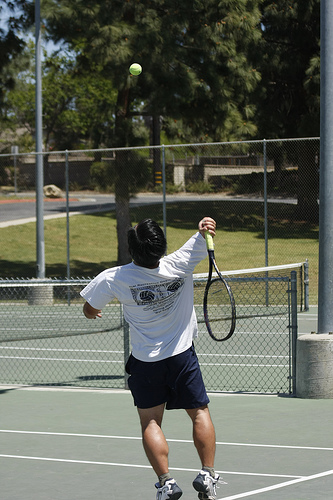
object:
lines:
[0, 427, 333, 500]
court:
[0, 134, 331, 498]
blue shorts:
[125, 340, 210, 410]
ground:
[264, 97, 288, 120]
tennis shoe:
[192, 467, 227, 500]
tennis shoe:
[155, 477, 183, 500]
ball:
[129, 63, 142, 75]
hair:
[127, 218, 167, 266]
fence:
[0, 259, 309, 397]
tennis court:
[0, 385, 333, 500]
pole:
[317, 0, 332, 333]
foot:
[192, 471, 220, 500]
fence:
[0, 136, 321, 393]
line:
[216, 442, 332, 451]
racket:
[203, 230, 236, 341]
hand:
[198, 216, 216, 238]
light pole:
[34, 0, 46, 281]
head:
[127, 218, 167, 265]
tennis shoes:
[155, 469, 227, 499]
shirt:
[79, 232, 210, 364]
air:
[0, 0, 333, 172]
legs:
[132, 369, 216, 482]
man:
[80, 217, 227, 500]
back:
[120, 272, 194, 362]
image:
[129, 277, 187, 318]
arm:
[172, 231, 207, 276]